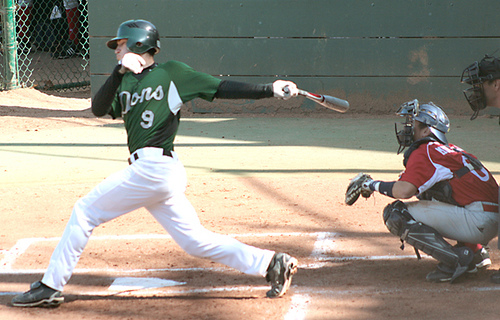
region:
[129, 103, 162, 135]
number on a jersey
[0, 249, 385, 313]
shadows on the ground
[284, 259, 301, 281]
cleats on the shoe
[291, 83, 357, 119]
bat in the air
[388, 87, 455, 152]
helmet on the boys head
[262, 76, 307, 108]
hand holding the bat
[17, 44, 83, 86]
wire mesh on the fence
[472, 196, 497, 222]
belt on the catcher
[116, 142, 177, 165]
belt loops on the player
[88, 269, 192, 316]
home base on the field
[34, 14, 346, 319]
baseball player swinging a bat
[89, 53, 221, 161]
a green top with white letters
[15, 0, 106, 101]
a fence in the background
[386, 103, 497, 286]
a catcher with a red top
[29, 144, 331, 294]
batter with clean white pants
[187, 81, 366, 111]
bat in left hand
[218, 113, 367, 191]
shadows on the brown dirt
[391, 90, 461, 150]
a catchers hard hat and face mask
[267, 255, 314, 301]
baseball players right shoe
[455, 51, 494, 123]
umpire with face mask on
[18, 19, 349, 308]
a man swinging a bat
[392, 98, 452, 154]
a man wearing a helmet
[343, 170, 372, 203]
a man's gloved hand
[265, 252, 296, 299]
a man's baseball cleat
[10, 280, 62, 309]
a man's baseball cleat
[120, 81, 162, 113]
white lettering on a green jersey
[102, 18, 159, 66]
green helmet on a man's head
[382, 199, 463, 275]
a man's shin guard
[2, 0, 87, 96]
a green metal fence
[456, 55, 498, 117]
an umpire with a mask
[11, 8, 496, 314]
people playing baseball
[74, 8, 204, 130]
man wears a helmet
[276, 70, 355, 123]
player holds a bat on left hand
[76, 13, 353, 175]
player wears a green shirt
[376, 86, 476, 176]
catcher wears a black helmet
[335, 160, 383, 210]
a brown baseball glove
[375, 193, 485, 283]
shin protectors on legs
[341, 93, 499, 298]
catcher sits squatting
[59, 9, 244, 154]
player is number 9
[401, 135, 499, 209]
red and white shirt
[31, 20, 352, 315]
a batter hitting a ball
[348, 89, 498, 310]
a catcher behind a batter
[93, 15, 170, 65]
a man in a black helmet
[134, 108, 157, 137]
the number 9 on a green shirt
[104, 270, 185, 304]
home plate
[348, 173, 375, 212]
a catcher's mit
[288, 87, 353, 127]
a bat that has just been swung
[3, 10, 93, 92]
a fence of a dug out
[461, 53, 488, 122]
an umpire mask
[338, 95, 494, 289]
a catcher in a red shirt